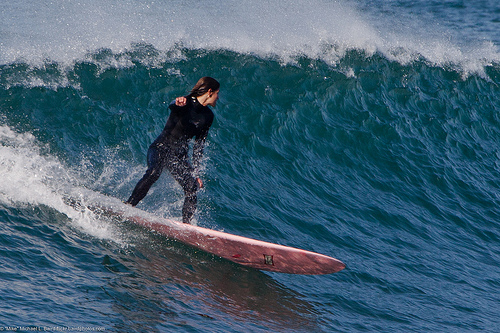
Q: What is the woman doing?
A: Surfing.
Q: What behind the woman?
A: Big wave.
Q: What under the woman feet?
A: Surfboard.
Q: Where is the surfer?
A: On a surfboard.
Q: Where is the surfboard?
A: In the ocean.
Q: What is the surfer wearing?
A: A wet suit.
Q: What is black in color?
A: The wet suit.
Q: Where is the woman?
A: On a surfboard.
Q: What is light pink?
A: The surfboard.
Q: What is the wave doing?
A: Cresting.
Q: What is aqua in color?
A: The water.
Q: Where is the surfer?
A: In the ocean.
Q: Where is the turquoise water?
A: Beside the surfer.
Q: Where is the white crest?
A: On top of the wave.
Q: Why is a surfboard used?
A: To ride waves.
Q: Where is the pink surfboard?
A: Under the woman.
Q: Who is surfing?
A: A woman.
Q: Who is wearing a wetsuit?
A: A woman.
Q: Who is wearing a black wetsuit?
A: The woman.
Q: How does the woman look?
A: Wet.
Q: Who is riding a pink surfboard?
A: A woman.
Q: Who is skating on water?
A: A woman.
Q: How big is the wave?
A: Very big.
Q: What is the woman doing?
A: Surfing.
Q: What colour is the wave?
A: Blue.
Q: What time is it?
A: 2:36 PM.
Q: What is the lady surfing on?
A: Surfboard.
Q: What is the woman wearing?
A: Wetsuit.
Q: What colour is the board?
A: Pink.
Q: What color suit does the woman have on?
A: Black.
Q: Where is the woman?
A: On surfboard.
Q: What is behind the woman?
A: A wave.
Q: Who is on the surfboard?
A: The woman is.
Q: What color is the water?
A: Blue.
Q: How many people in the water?
A: One.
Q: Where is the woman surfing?
A: In water.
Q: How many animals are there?
A: None.